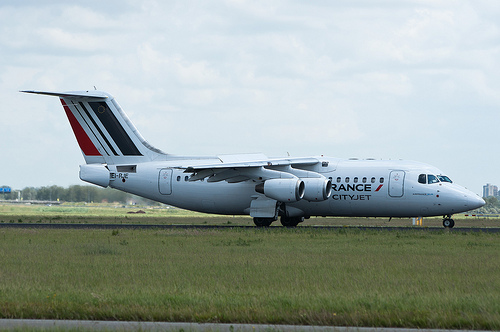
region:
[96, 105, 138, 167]
Black stripe on tail of plane.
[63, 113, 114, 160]
Red stripe on tail of plane.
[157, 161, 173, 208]
White door near back of plane.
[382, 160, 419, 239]
White door near front of plane.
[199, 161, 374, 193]
Windows a long the side of plane.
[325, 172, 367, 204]
Black writing on side of plane.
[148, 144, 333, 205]
White wing on side of plane.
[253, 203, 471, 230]
Landing gear is down on plane.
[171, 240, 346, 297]
Grassy area near airplane.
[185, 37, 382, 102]
White clouds in sky.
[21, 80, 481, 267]
an airplane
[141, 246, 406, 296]
the gras is tall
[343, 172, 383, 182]
the windows on the plane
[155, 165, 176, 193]
the backdoor of the airplane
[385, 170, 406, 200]
a door on the plane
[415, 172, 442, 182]
windshield of the plane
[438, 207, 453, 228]
the front tire on the plane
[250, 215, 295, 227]
back tires to the plane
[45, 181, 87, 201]
green trees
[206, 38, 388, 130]
white clouds in the sky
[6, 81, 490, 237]
a jet plane at the airport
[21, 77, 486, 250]
a jet plane on the ground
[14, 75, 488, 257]
a jet plane on the taxi way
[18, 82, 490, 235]
a jet plane on the tarmac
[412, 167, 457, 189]
windows for the pilots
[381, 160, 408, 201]
front door of the plane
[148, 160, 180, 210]
rear door of the plane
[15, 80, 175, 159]
tail fin of the plane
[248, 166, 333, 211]
two engines of the plane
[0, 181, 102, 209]
the trees in the distance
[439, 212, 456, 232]
Front tires on airplane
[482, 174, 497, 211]
Tall building behind airplane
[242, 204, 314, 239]
Back wheels on airplane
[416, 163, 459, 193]
Windows for cockpit area on airplane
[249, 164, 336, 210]
Engines on side of airplane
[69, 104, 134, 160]
Striped on side of airplane fin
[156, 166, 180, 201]
Back passenger loading door on airplane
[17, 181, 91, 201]
Row of trees behind airplane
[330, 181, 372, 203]
Logo on side of airplane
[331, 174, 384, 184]
Passenger windows on side of airplane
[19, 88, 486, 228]
airplane in runway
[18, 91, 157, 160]
red, white and blue tail of airplane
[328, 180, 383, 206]
name brand of plane printed on side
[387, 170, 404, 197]
front door of airplane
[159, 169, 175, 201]
back door of airplane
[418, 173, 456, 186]
front windows of the cockpit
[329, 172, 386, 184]
passenger windows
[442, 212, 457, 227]
front wheels under plane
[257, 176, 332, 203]
two engines under right wing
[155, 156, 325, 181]
right wing of airplane